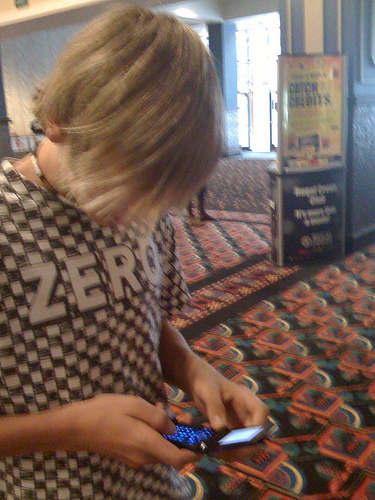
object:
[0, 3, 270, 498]
boy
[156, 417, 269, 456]
cell phone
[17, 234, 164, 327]
word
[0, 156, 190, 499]
shirt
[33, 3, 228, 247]
hair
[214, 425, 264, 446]
screen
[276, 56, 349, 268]
poster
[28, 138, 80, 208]
necklace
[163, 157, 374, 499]
carpet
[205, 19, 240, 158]
molding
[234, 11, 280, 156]
entry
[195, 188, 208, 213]
legs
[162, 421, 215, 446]
keypad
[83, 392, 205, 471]
hand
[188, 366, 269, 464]
hand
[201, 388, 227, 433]
thumb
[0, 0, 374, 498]
building